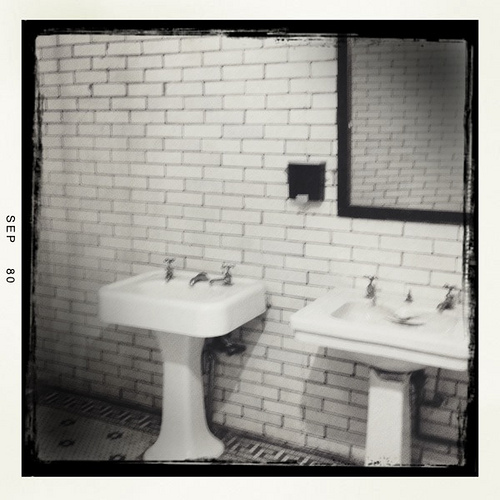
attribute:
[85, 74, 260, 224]
brick — white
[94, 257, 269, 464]
sink — white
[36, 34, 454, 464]
brick — white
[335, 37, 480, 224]
mirror — bathroom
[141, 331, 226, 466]
pedestal — white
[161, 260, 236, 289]
fawcets — chrome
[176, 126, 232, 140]
brick — white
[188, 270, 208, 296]
faucet — silver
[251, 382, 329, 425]
brick — white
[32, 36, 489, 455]
brick — white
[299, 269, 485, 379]
sink — wide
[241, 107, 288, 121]
brick — white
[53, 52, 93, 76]
brick — white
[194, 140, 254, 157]
brick — white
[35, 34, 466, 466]
photo — old, black, white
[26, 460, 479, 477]
border — black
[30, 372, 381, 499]
border — abstract